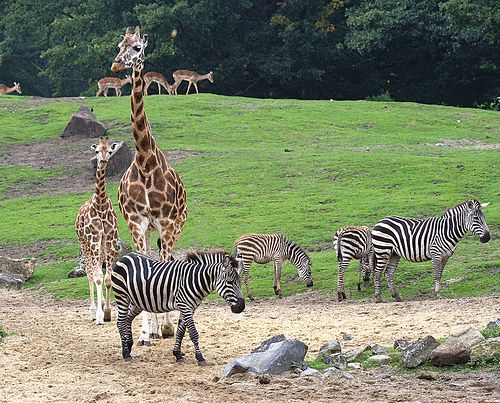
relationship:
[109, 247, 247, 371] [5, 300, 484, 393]
zebra standing in dirt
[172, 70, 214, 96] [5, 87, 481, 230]
deer standing on hill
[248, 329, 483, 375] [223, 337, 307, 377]
pile of rock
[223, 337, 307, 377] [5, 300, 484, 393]
rock in dirt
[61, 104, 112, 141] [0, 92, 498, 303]
rock on hill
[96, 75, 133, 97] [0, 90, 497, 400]
deer standing on grass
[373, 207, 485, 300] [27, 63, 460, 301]
zebra standing on field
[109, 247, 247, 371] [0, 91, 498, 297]
zebra standing on field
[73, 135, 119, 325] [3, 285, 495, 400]
baby walking in dirt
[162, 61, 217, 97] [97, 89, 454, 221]
deer walking on hill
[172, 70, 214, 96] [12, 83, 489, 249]
deer walking on hill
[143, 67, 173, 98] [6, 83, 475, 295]
deer grazing on hill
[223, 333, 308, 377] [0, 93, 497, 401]
rock on ground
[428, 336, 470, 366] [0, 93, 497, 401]
rock on ground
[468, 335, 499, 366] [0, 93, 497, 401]
rock on ground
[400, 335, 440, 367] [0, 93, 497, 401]
rock on ground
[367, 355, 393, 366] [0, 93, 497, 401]
rock on ground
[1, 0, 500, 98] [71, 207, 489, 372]
trees near animals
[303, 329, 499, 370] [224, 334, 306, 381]
grass growing around rock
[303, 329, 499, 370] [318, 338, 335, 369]
grass growing around rock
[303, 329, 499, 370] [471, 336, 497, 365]
grass growing around rock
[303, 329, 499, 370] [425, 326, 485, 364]
grass growing around rock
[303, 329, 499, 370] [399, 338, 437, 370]
grass growing around rock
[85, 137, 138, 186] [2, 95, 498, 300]
rock has no grass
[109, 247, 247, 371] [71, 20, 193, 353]
zebra and giraffe's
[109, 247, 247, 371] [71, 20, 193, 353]
zebra walking in front of giraffe's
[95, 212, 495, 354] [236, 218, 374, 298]
zebras are grazing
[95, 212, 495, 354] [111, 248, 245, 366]
zebras are walking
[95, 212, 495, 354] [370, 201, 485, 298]
zebras are walking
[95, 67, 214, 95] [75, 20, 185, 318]
deer behind giraffes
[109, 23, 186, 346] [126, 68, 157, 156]
adult has a long neck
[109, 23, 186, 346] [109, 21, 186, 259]
adult an adult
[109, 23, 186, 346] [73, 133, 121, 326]
adult a baby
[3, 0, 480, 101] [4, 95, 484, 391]
trees around clearing